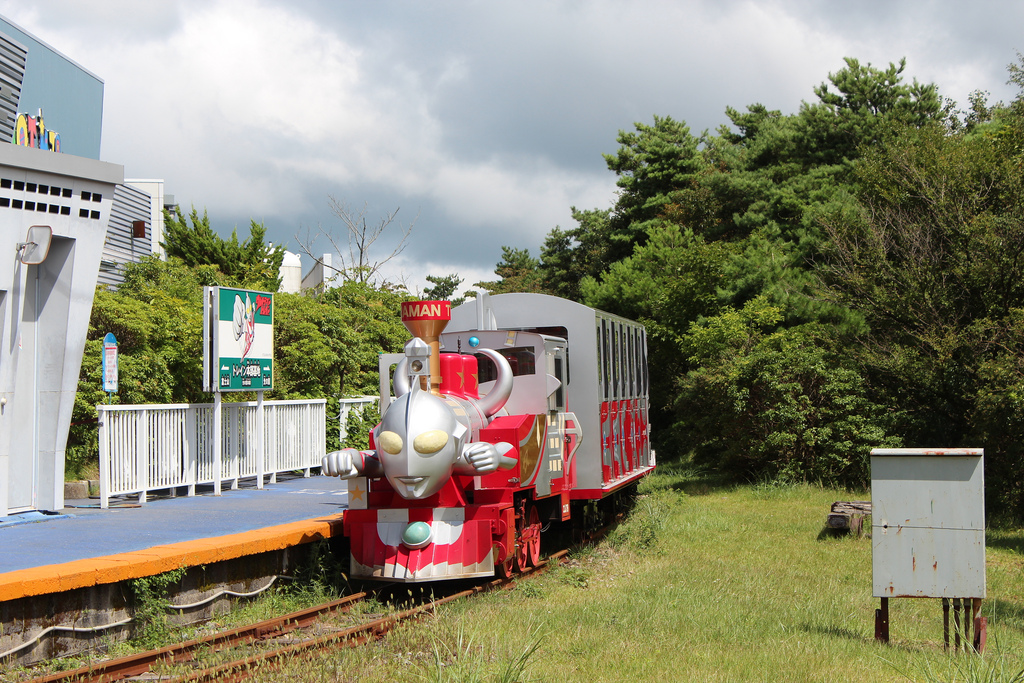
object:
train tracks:
[43, 553, 566, 677]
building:
[257, 240, 361, 288]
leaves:
[670, 317, 731, 352]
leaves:
[729, 399, 757, 429]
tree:
[592, 168, 912, 454]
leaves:
[874, 348, 917, 373]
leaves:
[954, 266, 989, 306]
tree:
[845, 73, 966, 488]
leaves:
[832, 97, 886, 146]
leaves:
[781, 304, 846, 342]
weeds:
[343, 635, 460, 674]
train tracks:
[228, 589, 422, 654]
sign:
[103, 332, 122, 393]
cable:
[11, 564, 298, 658]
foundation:
[11, 530, 332, 654]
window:
[18, 175, 27, 189]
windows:
[24, 185, 43, 193]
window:
[81, 193, 94, 201]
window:
[94, 194, 97, 198]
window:
[2, 194, 17, 209]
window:
[95, 213, 104, 218]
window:
[84, 208, 97, 216]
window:
[61, 208, 75, 220]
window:
[48, 206, 67, 214]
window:
[15, 198, 34, 214]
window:
[26, 200, 37, 213]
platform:
[90, 461, 345, 501]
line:
[41, 523, 244, 560]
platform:
[46, 469, 273, 565]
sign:
[206, 286, 275, 395]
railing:
[98, 406, 189, 505]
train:
[321, 290, 653, 580]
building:
[0, 147, 117, 516]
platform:
[54, 500, 336, 537]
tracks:
[129, 595, 469, 660]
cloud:
[266, 22, 394, 189]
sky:
[444, 29, 589, 116]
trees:
[91, 207, 274, 480]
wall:
[7, 222, 75, 507]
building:
[2, 4, 180, 521]